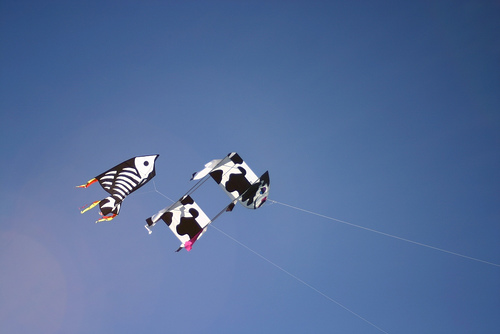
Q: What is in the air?
A: Kites.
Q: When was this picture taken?
A: During the day.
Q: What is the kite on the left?
A: A fish.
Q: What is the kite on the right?
A: A cow.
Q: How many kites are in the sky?
A: Two.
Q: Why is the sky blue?
A: It's daylight.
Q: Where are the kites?
A: In the sky.